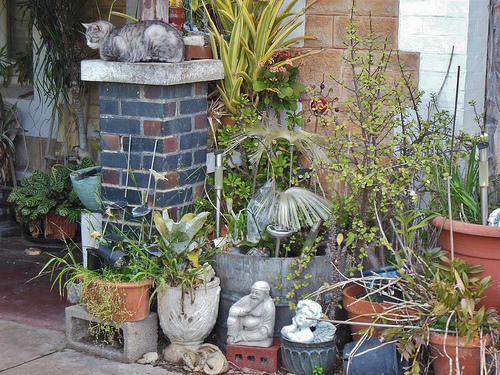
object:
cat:
[79, 20, 184, 64]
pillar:
[81, 58, 225, 242]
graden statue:
[226, 279, 277, 348]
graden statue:
[281, 298, 339, 344]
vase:
[156, 277, 221, 364]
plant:
[147, 210, 222, 308]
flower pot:
[349, 337, 412, 365]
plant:
[84, 273, 147, 340]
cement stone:
[63, 303, 160, 363]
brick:
[232, 353, 272, 364]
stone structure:
[239, 264, 294, 285]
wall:
[261, 0, 486, 211]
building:
[284, 0, 486, 256]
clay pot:
[47, 211, 75, 240]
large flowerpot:
[426, 214, 500, 317]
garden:
[203, 1, 492, 370]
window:
[1, 0, 37, 101]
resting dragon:
[183, 342, 232, 374]